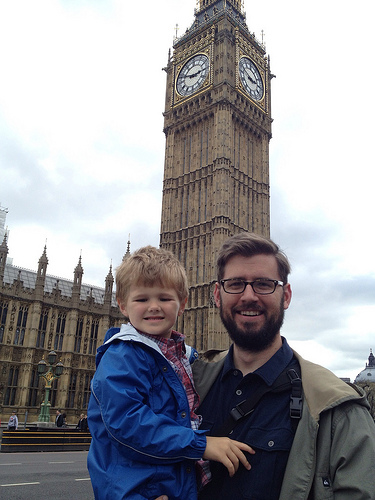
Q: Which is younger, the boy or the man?
A: The boy is younger than the man.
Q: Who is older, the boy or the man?
A: The man is older than the boy.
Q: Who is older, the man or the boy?
A: The man is older than the boy.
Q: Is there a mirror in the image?
A: No, there are no mirrors.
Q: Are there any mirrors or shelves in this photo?
A: No, there are no mirrors or shelves.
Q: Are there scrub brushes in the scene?
A: No, there are no scrub brushes.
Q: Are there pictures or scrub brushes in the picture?
A: No, there are no scrub brushes or pictures.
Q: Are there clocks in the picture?
A: Yes, there is a clock.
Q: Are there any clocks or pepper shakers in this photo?
A: Yes, there is a clock.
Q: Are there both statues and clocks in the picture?
A: No, there is a clock but no statues.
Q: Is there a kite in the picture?
A: No, there are no kites.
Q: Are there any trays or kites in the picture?
A: No, there are no kites or trays.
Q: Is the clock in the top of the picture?
A: Yes, the clock is in the top of the image.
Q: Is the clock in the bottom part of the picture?
A: No, the clock is in the top of the image.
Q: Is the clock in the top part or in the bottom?
A: The clock is in the top of the image.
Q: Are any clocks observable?
A: Yes, there is a clock.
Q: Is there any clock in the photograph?
A: Yes, there is a clock.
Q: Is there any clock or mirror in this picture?
A: Yes, there is a clock.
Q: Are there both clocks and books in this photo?
A: No, there is a clock but no books.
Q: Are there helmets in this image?
A: No, there are no helmets.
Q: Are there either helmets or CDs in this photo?
A: No, there are no helmets or cds.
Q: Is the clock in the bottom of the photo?
A: No, the clock is in the top of the image.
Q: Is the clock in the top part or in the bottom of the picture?
A: The clock is in the top of the image.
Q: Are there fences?
A: No, there are no fences.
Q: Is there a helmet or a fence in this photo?
A: No, there are no fences or helmets.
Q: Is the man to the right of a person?
A: Yes, the man is to the right of a person.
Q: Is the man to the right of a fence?
A: No, the man is to the right of a person.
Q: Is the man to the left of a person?
A: No, the man is to the right of a person.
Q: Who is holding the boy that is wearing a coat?
A: The man is holding the boy.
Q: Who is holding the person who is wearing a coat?
A: The man is holding the boy.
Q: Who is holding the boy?
A: The man is holding the boy.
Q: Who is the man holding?
A: The man is holding the boy.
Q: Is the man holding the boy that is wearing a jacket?
A: Yes, the man is holding the boy.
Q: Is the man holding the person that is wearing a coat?
A: Yes, the man is holding the boy.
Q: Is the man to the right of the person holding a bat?
A: No, the man is holding the boy.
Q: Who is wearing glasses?
A: The man is wearing glasses.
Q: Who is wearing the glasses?
A: The man is wearing glasses.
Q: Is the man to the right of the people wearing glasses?
A: Yes, the man is wearing glasses.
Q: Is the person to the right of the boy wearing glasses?
A: Yes, the man is wearing glasses.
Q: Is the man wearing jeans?
A: No, the man is wearing glasses.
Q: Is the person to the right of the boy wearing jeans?
A: No, the man is wearing glasses.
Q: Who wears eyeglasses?
A: The man wears eyeglasses.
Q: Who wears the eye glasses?
A: The man wears eyeglasses.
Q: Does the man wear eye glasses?
A: Yes, the man wears eye glasses.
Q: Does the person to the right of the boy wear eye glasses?
A: Yes, the man wears eye glasses.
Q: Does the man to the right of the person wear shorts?
A: No, the man wears eye glasses.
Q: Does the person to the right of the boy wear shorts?
A: No, the man wears eye glasses.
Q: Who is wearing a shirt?
A: The man is wearing a shirt.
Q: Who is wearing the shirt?
A: The man is wearing a shirt.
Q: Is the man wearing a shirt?
A: Yes, the man is wearing a shirt.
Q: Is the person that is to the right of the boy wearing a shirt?
A: Yes, the man is wearing a shirt.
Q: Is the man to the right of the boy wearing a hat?
A: No, the man is wearing a shirt.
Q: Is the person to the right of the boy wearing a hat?
A: No, the man is wearing a shirt.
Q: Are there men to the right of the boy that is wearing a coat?
A: Yes, there is a man to the right of the boy.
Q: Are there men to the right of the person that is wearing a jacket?
A: Yes, there is a man to the right of the boy.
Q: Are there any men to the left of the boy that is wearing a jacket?
A: No, the man is to the right of the boy.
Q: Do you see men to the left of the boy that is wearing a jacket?
A: No, the man is to the right of the boy.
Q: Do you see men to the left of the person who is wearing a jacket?
A: No, the man is to the right of the boy.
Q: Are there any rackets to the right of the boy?
A: No, there is a man to the right of the boy.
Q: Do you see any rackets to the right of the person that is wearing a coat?
A: No, there is a man to the right of the boy.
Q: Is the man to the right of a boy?
A: Yes, the man is to the right of a boy.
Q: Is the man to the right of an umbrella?
A: No, the man is to the right of a boy.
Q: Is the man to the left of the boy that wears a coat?
A: No, the man is to the right of the boy.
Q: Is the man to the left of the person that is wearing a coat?
A: No, the man is to the right of the boy.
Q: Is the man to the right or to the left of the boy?
A: The man is to the right of the boy.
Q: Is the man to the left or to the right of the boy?
A: The man is to the right of the boy.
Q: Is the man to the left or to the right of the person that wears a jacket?
A: The man is to the right of the boy.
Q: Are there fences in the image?
A: No, there are no fences.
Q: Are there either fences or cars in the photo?
A: No, there are no fences or cars.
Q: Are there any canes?
A: No, there are no canes.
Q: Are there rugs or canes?
A: No, there are no canes or rugs.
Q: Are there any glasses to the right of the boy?
A: Yes, there are glasses to the right of the boy.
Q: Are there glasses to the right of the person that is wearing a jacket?
A: Yes, there are glasses to the right of the boy.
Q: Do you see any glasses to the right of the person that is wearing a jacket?
A: Yes, there are glasses to the right of the boy.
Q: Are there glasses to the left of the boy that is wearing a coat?
A: No, the glasses are to the right of the boy.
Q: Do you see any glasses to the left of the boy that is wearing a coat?
A: No, the glasses are to the right of the boy.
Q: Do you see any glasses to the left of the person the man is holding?
A: No, the glasses are to the right of the boy.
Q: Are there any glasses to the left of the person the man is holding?
A: No, the glasses are to the right of the boy.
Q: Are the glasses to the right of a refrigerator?
A: No, the glasses are to the right of the boy.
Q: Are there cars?
A: No, there are no cars.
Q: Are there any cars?
A: No, there are no cars.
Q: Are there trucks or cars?
A: No, there are no cars or trucks.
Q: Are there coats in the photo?
A: Yes, there is a coat.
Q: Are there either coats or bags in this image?
A: Yes, there is a coat.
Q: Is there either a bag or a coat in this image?
A: Yes, there is a coat.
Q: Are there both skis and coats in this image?
A: No, there is a coat but no skis.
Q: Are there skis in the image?
A: No, there are no skis.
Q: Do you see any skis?
A: No, there are no skis.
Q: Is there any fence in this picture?
A: No, there are no fences.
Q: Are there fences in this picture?
A: No, there are no fences.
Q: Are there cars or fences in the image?
A: No, there are no fences or cars.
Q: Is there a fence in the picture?
A: No, there are no fences.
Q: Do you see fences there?
A: No, there are no fences.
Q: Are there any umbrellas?
A: No, there are no umbrellas.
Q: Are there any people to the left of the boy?
A: Yes, there are people to the left of the boy.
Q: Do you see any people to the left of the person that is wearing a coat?
A: Yes, there are people to the left of the boy.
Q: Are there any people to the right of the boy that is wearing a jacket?
A: No, the people are to the left of the boy.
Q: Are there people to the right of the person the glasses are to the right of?
A: No, the people are to the left of the boy.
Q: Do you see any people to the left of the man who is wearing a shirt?
A: Yes, there are people to the left of the man.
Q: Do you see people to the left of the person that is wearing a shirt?
A: Yes, there are people to the left of the man.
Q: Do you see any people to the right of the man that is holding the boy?
A: No, the people are to the left of the man.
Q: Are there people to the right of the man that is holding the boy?
A: No, the people are to the left of the man.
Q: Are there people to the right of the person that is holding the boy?
A: No, the people are to the left of the man.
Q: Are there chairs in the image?
A: No, there are no chairs.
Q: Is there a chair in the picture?
A: No, there are no chairs.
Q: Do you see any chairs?
A: No, there are no chairs.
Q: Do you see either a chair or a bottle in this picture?
A: No, there are no chairs or bottles.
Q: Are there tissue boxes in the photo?
A: No, there are no tissue boxes.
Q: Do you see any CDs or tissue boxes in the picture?
A: No, there are no tissue boxes or cds.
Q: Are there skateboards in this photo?
A: No, there are no skateboards.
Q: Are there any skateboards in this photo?
A: No, there are no skateboards.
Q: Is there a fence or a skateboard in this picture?
A: No, there are no skateboards or fences.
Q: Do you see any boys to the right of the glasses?
A: No, the boy is to the left of the glasses.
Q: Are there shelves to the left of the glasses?
A: No, there is a boy to the left of the glasses.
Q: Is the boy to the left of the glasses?
A: Yes, the boy is to the left of the glasses.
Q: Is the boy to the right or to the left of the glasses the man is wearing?
A: The boy is to the left of the glasses.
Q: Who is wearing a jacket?
A: The boy is wearing a jacket.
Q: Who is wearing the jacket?
A: The boy is wearing a jacket.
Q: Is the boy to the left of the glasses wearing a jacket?
A: Yes, the boy is wearing a jacket.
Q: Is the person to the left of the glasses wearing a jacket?
A: Yes, the boy is wearing a jacket.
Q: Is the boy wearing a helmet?
A: No, the boy is wearing a jacket.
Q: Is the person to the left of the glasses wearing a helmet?
A: No, the boy is wearing a jacket.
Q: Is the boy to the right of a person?
A: Yes, the boy is to the right of a person.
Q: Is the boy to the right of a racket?
A: No, the boy is to the right of a person.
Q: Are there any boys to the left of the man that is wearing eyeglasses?
A: Yes, there is a boy to the left of the man.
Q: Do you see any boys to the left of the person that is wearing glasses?
A: Yes, there is a boy to the left of the man.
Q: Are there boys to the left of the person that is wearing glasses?
A: Yes, there is a boy to the left of the man.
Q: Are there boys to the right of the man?
A: No, the boy is to the left of the man.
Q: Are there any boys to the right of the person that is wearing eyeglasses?
A: No, the boy is to the left of the man.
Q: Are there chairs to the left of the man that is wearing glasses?
A: No, there is a boy to the left of the man.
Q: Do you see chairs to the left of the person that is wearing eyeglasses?
A: No, there is a boy to the left of the man.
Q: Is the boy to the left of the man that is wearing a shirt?
A: Yes, the boy is to the left of the man.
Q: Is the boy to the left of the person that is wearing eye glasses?
A: Yes, the boy is to the left of the man.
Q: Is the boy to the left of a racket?
A: No, the boy is to the left of the man.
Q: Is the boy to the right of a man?
A: No, the boy is to the left of a man.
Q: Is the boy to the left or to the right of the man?
A: The boy is to the left of the man.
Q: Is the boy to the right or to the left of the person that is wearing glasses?
A: The boy is to the left of the man.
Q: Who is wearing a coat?
A: The boy is wearing a coat.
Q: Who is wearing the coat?
A: The boy is wearing a coat.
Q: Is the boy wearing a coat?
A: Yes, the boy is wearing a coat.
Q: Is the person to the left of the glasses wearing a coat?
A: Yes, the boy is wearing a coat.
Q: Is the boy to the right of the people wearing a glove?
A: No, the boy is wearing a coat.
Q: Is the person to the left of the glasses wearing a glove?
A: No, the boy is wearing a coat.